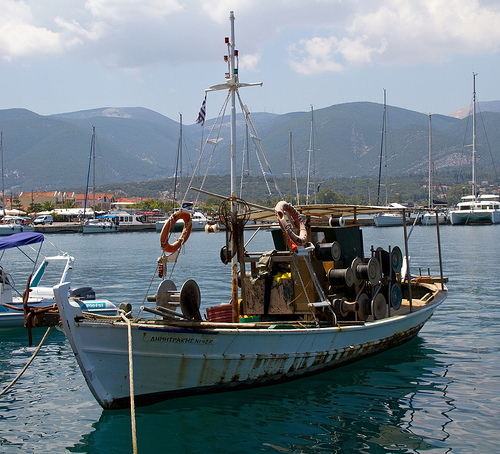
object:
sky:
[1, 0, 500, 124]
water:
[0, 224, 500, 452]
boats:
[0, 251, 117, 331]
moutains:
[446, 99, 500, 119]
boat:
[449, 73, 500, 225]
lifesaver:
[157, 211, 193, 252]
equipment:
[276, 198, 308, 243]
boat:
[54, 11, 448, 412]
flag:
[194, 92, 207, 124]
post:
[229, 11, 238, 322]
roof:
[1, 231, 45, 249]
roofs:
[73, 192, 114, 198]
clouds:
[285, 1, 500, 82]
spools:
[324, 266, 352, 288]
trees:
[39, 197, 57, 211]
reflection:
[71, 343, 450, 454]